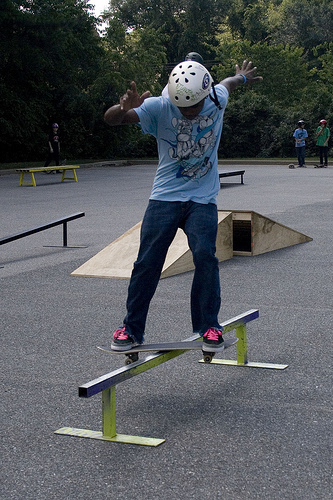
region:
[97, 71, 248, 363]
person on skateboard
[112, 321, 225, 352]
tennis shoes with pink strings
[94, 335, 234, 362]
black skateboard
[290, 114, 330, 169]
two people on skateboards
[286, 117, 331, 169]
people in skateboard park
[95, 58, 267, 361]
person performing trick on skateboard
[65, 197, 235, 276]
ramp for skateboarding tricks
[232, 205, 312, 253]
ramp in skateboard park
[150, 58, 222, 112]
white helmet on boy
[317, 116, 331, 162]
boy in red shirt in skateboard park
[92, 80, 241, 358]
A person with skateboard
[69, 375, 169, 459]
A green color metal rod with stand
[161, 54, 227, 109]
A person wearing helmet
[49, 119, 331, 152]
Lot of people standing in the floor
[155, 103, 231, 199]
A person wearing blue color round neck t-shirt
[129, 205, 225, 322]
A person wearing blue color jean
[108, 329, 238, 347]
Pair of shoes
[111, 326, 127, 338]
Pink color shoe lace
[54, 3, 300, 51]
Lot of trees with branches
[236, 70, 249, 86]
A person wearing wrist band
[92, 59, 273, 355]
Young man doing stunt on skateboard.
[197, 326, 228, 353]
Young man wearing black tennis shoes with pink shoe laces.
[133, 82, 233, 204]
Young man dressed in blue t-shirt.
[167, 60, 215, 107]
Young man wearing safety helmet.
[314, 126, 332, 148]
Person in background dressed in green t-shirt.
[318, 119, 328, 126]
Person in background wearing red safety helmet.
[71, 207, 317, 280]
Wood skateboard ramp in park.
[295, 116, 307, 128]
Person in background wearing black safety helmet.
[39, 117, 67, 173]
Young man in background walking across skateboard park.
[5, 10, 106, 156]
Trees growing at end of skateboard park.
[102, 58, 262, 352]
Man on a skateboard.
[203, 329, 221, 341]
The pink shoelaces.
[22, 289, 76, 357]
Part of the road.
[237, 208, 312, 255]
Part of the skateboard jump.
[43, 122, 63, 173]
A person watching in the background.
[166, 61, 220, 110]
A white helmet on the person's head.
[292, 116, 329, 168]
Two people talking in the background.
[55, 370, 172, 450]
Part of a metal jump.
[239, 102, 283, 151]
The trees in the background.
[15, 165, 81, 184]
A long yellow skateboard jump.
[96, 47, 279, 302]
Boy in blue shirt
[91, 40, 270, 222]
Boy wearing white helmet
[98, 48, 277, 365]
Boy wearing blue jeans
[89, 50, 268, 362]
Boy wearing black shoes with pink laces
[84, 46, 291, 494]
Boy doing tricks on skateboard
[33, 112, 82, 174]
Boy in black shirt and pants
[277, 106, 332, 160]
Two boys talking to each other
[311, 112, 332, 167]
Boy wearing green shirt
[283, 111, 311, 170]
Boy wearing blue shirt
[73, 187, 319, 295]
Ramp for skateboarding tricks